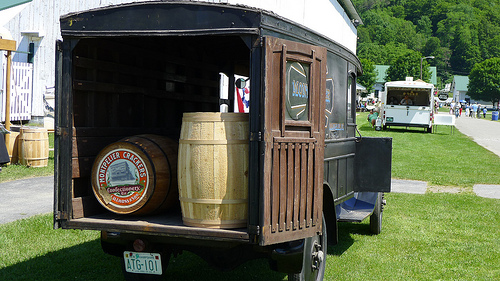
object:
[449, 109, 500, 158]
sidewalk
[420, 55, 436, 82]
street lamp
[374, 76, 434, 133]
truck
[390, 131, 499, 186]
grass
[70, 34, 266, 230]
door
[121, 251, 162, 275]
license plate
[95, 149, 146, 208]
label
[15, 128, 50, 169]
barrel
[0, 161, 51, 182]
grass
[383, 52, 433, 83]
trees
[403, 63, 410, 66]
leaves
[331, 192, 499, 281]
grass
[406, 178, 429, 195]
stone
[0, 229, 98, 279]
grass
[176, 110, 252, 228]
barrel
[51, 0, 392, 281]
car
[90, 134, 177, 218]
barrel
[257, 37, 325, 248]
doors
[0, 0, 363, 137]
barn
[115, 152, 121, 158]
lettering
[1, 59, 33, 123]
fence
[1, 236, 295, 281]
shadow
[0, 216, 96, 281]
ground